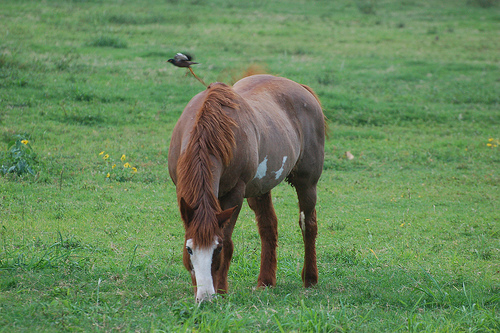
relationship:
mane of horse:
[190, 84, 240, 172] [184, 72, 322, 274]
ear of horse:
[215, 200, 245, 231] [184, 72, 322, 274]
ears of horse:
[179, 197, 195, 225] [184, 72, 322, 274]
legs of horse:
[295, 182, 318, 287] [184, 72, 322, 274]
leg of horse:
[255, 191, 278, 287] [184, 72, 322, 274]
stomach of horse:
[246, 152, 294, 198] [184, 72, 322, 274]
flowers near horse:
[94, 146, 135, 172] [184, 72, 322, 274]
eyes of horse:
[182, 236, 220, 258] [184, 72, 322, 274]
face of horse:
[187, 234, 218, 299] [184, 72, 322, 274]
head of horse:
[174, 184, 239, 310] [184, 72, 322, 274]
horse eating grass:
[184, 72, 322, 274] [19, 248, 474, 328]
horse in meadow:
[184, 72, 322, 274] [11, 7, 480, 331]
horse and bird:
[184, 72, 322, 274] [171, 40, 197, 73]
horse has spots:
[184, 72, 322, 274] [242, 153, 318, 190]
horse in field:
[184, 72, 322, 274] [10, 16, 488, 333]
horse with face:
[184, 72, 322, 274] [187, 234, 218, 299]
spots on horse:
[242, 153, 318, 190] [184, 72, 322, 274]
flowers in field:
[94, 146, 135, 172] [10, 16, 488, 333]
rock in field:
[339, 148, 361, 167] [10, 16, 488, 333]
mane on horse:
[190, 84, 240, 172] [184, 72, 322, 274]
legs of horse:
[201, 178, 325, 299] [184, 72, 322, 274]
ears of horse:
[176, 201, 245, 225] [184, 72, 322, 274]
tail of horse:
[303, 77, 335, 137] [184, 72, 322, 274]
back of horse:
[239, 65, 300, 116] [184, 72, 322, 274]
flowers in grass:
[94, 146, 135, 172] [19, 248, 474, 328]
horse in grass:
[184, 72, 322, 274] [19, 248, 474, 328]